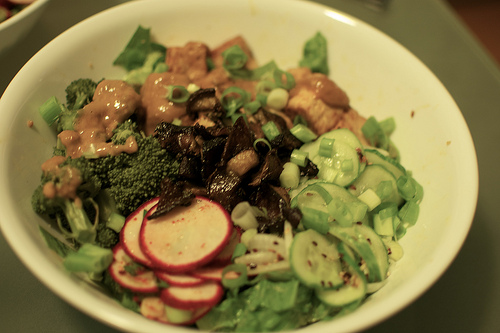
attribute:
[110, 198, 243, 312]
slices — radish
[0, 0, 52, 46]
bowl — edge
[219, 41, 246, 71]
green onion — chopped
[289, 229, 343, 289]
cucumber — slices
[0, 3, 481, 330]
bowl — side, white